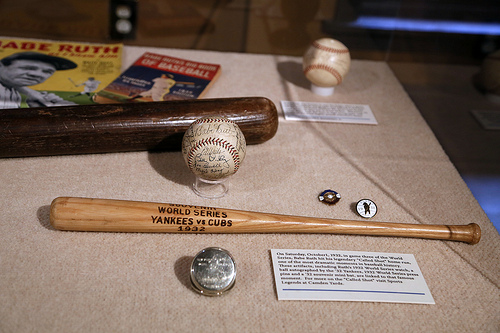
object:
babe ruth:
[0, 51, 78, 108]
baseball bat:
[0, 96, 278, 159]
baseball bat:
[49, 196, 481, 246]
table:
[3, 47, 499, 332]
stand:
[192, 176, 229, 199]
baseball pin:
[318, 189, 341, 204]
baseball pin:
[355, 198, 377, 217]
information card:
[280, 100, 378, 125]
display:
[0, 0, 495, 330]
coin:
[189, 247, 237, 297]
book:
[98, 50, 222, 104]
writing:
[277, 252, 420, 285]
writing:
[184, 144, 237, 176]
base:
[310, 83, 333, 96]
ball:
[303, 38, 351, 87]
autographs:
[199, 143, 223, 162]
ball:
[181, 116, 247, 180]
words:
[151, 203, 233, 230]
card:
[271, 249, 436, 305]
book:
[0, 37, 122, 108]